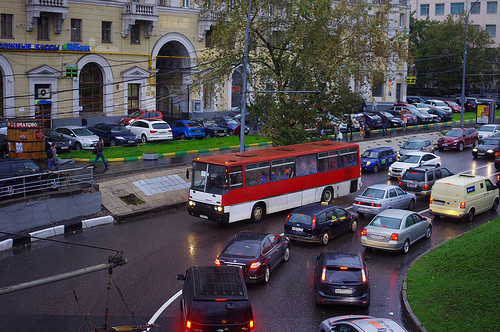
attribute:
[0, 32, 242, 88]
wire — electrical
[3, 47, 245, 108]
wire — electrical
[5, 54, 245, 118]
wire — electrical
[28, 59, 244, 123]
wire — electrical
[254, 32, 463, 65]
wire — electrical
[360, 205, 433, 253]
car — silver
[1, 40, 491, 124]
wires — electrical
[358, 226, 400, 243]
tail lights — red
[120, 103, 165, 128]
car — red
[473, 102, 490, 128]
sign — advertisement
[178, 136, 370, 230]
bus — red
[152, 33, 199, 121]
arch — large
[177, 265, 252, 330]
car — turning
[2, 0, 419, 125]
building — yellow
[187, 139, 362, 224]
bus — red and white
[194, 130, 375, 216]
bus — red and white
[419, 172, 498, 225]
car — cream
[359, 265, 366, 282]
light — on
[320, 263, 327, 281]
light — on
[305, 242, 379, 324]
car — turning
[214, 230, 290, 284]
car — driving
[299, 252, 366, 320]
car — black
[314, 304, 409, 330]
car — silver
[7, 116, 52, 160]
sign — wood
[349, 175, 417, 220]
car — silver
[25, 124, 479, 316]
road — curved